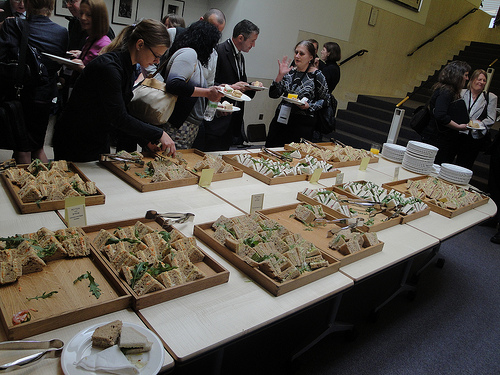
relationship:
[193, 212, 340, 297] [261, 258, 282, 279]
box of sandwich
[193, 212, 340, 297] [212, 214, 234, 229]
box of sandwich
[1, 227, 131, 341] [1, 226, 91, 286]
box of sandwiches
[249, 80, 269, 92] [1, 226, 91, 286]
plate of sandwiches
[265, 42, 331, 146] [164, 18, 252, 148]
woman holding plate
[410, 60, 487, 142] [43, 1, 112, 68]
woman holding plate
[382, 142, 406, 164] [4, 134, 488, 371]
plates on table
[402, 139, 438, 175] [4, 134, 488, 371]
plates on table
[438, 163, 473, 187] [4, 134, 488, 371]
plates on table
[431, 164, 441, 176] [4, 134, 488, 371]
plates on table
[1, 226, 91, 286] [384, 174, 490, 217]
sandwiches in boxes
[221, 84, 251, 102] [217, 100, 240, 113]
sandwiches on plate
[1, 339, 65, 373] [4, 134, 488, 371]
tong on table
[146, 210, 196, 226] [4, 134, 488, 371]
tong on table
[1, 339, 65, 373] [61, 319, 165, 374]
tongs near plate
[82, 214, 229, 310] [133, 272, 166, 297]
tray of sandwiches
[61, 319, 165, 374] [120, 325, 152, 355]
plate with sandwich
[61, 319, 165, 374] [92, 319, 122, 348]
plate with sandwich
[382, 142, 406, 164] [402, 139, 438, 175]
stack of plates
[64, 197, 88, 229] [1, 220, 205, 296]
card saying sandwiches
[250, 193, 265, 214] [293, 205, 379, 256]
card saying sandwiches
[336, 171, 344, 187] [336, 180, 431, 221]
card saying sandwiches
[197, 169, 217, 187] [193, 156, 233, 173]
card saying sandwiches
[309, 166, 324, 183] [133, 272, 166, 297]
card saying sandwiches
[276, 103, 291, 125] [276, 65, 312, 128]
badge around neck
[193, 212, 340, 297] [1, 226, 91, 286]
box of sandwiches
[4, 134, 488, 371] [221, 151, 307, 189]
table with sandwiches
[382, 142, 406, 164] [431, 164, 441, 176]
stack of plates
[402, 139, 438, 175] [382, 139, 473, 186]
stack of plates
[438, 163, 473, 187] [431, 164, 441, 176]
stack of plates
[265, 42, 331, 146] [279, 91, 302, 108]
woman with plate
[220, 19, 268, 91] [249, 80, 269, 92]
man with plate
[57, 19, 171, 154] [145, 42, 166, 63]
woman with glasses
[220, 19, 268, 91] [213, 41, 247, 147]
man in suit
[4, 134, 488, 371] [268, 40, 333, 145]
sandwiches for woman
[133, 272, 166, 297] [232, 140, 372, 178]
sandwiches to eat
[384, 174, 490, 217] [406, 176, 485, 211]
tray of food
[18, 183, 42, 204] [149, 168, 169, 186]
triangle shaped sandwich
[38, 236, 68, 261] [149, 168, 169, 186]
triangle shaped sandwich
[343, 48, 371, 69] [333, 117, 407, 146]
rail on stair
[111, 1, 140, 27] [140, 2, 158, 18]
photo on wall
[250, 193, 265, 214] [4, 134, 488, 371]
cardboard on table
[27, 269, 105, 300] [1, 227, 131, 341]
herb on tray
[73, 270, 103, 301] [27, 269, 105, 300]
green leafy herb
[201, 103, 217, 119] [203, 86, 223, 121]
water in bottle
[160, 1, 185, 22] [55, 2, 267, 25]
picture hanging on wall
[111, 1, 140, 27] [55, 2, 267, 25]
picture hanging on wall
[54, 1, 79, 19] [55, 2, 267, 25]
picture hanging on wall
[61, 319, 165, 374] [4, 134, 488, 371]
plate on table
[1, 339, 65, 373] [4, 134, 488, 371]
tong are on table